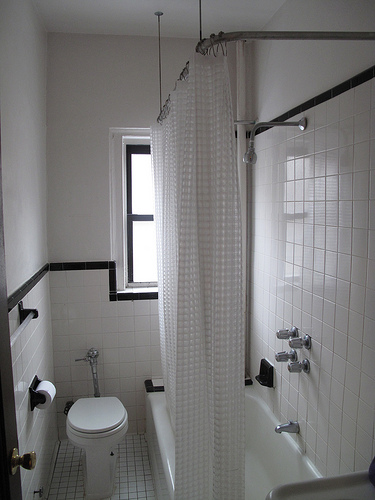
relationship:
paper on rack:
[36, 380, 57, 403] [26, 374, 47, 410]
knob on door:
[14, 453, 37, 474] [3, 277, 26, 498]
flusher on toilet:
[76, 346, 89, 368] [67, 399, 136, 461]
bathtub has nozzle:
[152, 394, 282, 499] [272, 417, 301, 440]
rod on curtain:
[156, 30, 226, 100] [138, 109, 257, 379]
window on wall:
[111, 129, 162, 296] [12, 14, 170, 292]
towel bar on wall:
[7, 307, 30, 349] [9, 277, 117, 370]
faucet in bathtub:
[272, 417, 301, 440] [152, 394, 282, 499]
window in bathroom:
[111, 129, 162, 296] [7, 13, 360, 486]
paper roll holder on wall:
[30, 375, 40, 415] [17, 371, 62, 480]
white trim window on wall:
[111, 129, 162, 296] [12, 14, 170, 292]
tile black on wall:
[56, 259, 113, 271] [43, 237, 107, 280]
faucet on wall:
[272, 417, 301, 440] [245, 143, 374, 448]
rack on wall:
[26, 374, 47, 410] [13, 292, 54, 410]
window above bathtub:
[111, 129, 162, 296] [152, 394, 282, 499]